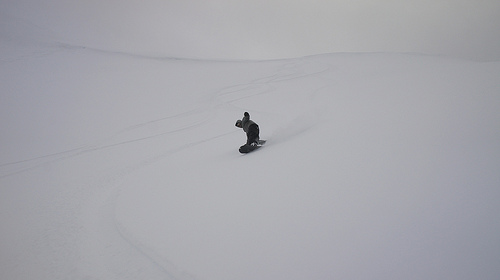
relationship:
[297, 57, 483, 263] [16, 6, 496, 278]
snow covering ground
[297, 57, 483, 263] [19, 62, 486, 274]
snow covering ground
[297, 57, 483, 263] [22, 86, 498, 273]
snow covering ground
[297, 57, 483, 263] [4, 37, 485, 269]
snow covering ground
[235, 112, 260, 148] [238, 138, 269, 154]
man on board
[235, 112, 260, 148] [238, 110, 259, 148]
man in gear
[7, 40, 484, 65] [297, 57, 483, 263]
line of snow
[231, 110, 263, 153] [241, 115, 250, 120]
man with arm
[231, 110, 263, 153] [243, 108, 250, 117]
man with hand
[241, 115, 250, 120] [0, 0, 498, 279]
arm in air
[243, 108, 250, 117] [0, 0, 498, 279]
hand in air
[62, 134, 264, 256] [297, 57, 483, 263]
lines in snow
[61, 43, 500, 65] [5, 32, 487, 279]
line on mountain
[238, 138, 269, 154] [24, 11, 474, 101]
board on a slope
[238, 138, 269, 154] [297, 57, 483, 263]
board on snow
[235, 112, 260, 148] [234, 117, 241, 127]
man with hair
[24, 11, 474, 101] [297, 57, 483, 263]
slope covered with snow